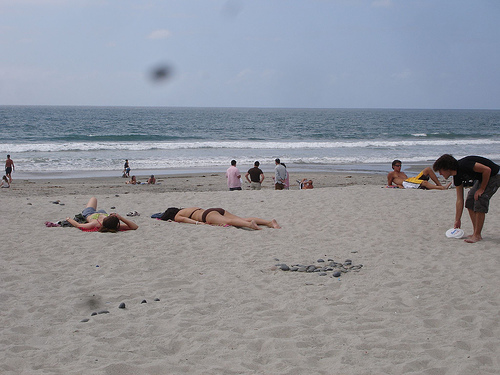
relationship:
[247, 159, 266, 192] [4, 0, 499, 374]
person at beach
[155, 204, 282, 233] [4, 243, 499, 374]
lady laying on beach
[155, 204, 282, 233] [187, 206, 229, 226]
lady wearing a bikini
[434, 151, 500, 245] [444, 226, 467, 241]
guy picking up frisbee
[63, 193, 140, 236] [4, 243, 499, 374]
person laying on beach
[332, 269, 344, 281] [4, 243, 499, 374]
rock on top of beach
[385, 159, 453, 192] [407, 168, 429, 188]
guy wearing shorts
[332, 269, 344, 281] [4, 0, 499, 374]
rock on top of beach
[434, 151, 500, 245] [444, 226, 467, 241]
guy picking up a frisbee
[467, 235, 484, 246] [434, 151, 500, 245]
foot of guy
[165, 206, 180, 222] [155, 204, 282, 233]
head of a lady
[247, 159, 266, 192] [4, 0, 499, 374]
person hanging on beach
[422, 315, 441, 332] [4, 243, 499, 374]
footprint on top of beach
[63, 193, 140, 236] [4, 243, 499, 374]
person laying down on beach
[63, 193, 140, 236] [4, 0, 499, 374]
person laying on beach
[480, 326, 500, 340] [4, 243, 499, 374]
footprint inside of beach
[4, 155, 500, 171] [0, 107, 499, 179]
wave rolling in water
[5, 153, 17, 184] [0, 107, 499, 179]
man going into water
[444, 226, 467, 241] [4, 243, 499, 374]
frisbee on top of beach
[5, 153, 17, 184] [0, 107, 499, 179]
man near water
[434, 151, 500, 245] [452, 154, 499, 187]
guy wearing shirt